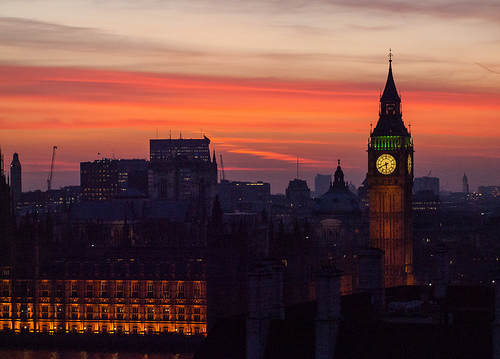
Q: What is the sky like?
A: Sunset.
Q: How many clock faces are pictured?
A: Two.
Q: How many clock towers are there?
A: One.